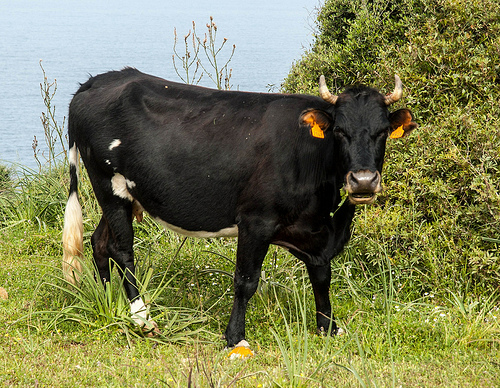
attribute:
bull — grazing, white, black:
[59, 68, 413, 353]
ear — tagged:
[297, 103, 331, 139]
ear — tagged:
[389, 105, 416, 141]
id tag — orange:
[313, 115, 326, 138]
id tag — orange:
[391, 115, 409, 135]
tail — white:
[62, 113, 78, 284]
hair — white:
[57, 192, 84, 285]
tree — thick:
[272, 3, 499, 295]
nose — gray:
[350, 171, 379, 192]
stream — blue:
[2, 2, 325, 203]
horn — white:
[385, 71, 404, 107]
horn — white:
[318, 73, 343, 104]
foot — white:
[132, 295, 157, 333]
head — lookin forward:
[328, 88, 390, 207]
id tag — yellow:
[227, 347, 250, 354]